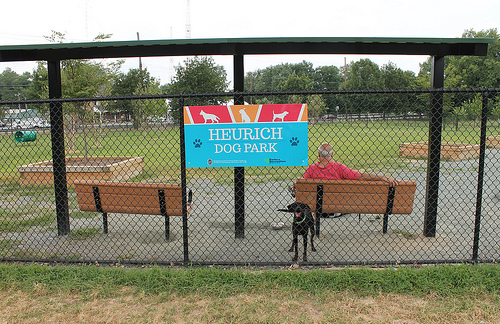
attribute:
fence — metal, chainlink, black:
[1, 87, 499, 267]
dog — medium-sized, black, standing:
[277, 201, 319, 265]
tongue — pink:
[293, 212, 301, 220]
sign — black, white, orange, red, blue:
[183, 104, 312, 170]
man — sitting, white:
[288, 142, 399, 195]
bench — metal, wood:
[290, 178, 420, 232]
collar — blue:
[291, 216, 310, 224]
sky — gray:
[2, 3, 499, 74]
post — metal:
[177, 97, 192, 263]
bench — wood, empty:
[73, 178, 196, 239]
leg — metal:
[382, 213, 391, 234]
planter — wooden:
[19, 155, 147, 188]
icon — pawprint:
[288, 134, 301, 149]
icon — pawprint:
[190, 137, 202, 149]